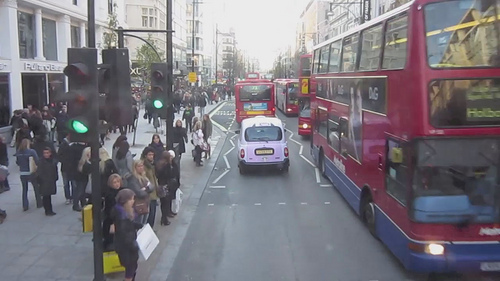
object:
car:
[236, 114, 290, 175]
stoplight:
[72, 118, 93, 133]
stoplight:
[153, 99, 165, 110]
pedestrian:
[34, 145, 59, 218]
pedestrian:
[13, 138, 42, 212]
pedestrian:
[110, 187, 143, 279]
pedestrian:
[139, 132, 168, 164]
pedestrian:
[114, 139, 137, 191]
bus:
[232, 78, 275, 122]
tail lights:
[284, 147, 289, 157]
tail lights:
[240, 149, 244, 158]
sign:
[188, 71, 197, 83]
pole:
[183, 0, 200, 91]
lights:
[62, 65, 173, 136]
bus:
[308, 0, 496, 280]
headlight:
[428, 243, 445, 256]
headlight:
[302, 124, 308, 129]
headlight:
[287, 108, 293, 111]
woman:
[105, 194, 168, 280]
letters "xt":
[129, 63, 142, 75]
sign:
[128, 62, 144, 77]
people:
[114, 188, 139, 276]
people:
[157, 150, 175, 224]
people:
[170, 120, 184, 168]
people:
[37, 147, 60, 216]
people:
[0, 73, 229, 280]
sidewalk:
[0, 81, 229, 281]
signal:
[64, 47, 99, 140]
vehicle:
[237, 115, 291, 175]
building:
[155, 0, 243, 107]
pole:
[87, 2, 102, 279]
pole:
[161, 0, 172, 145]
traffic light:
[64, 47, 96, 139]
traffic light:
[100, 44, 136, 131]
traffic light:
[148, 63, 170, 118]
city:
[0, 0, 498, 280]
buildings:
[429, 4, 497, 116]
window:
[421, 0, 498, 72]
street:
[156, 82, 395, 279]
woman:
[15, 137, 41, 212]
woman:
[169, 117, 188, 168]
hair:
[116, 188, 136, 206]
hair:
[77, 147, 92, 172]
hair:
[19, 138, 31, 149]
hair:
[116, 140, 129, 161]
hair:
[15, 109, 23, 115]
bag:
[81, 206, 95, 233]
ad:
[368, 86, 380, 100]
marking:
[202, 98, 236, 190]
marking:
[286, 120, 329, 188]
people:
[10, 103, 102, 215]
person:
[111, 188, 148, 280]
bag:
[129, 221, 159, 261]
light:
[153, 100, 165, 110]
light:
[72, 118, 90, 134]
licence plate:
[254, 147, 275, 155]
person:
[14, 137, 40, 210]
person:
[55, 133, 79, 203]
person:
[72, 141, 90, 211]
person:
[111, 138, 138, 174]